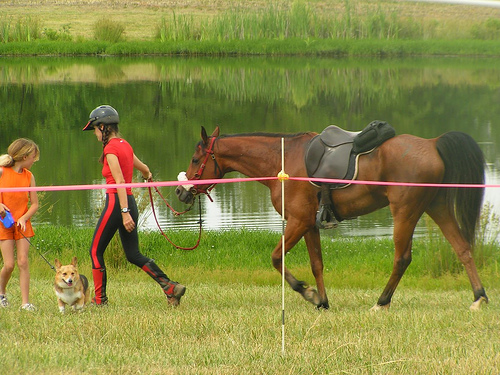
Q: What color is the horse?
A: Brown.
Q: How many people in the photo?
A: Two.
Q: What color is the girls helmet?
A: Black.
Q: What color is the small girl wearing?
A: Orange.